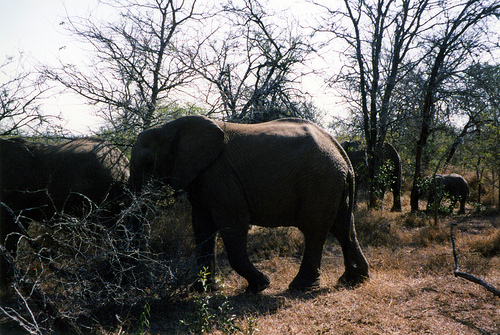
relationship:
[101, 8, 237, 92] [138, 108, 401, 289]
tree behind elephant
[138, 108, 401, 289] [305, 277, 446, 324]
elephant on ground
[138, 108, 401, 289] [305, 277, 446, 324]
elephant above ground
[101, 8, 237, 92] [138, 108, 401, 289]
tree near elephant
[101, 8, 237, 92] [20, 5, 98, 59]
tree in sky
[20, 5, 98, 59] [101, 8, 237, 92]
sky near tree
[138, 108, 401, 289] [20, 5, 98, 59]
elephant near sky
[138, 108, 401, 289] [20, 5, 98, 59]
elephant below sky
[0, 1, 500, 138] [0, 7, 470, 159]
sky between trees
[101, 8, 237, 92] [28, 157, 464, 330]
tree on ground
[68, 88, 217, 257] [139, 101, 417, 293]
head of elephant